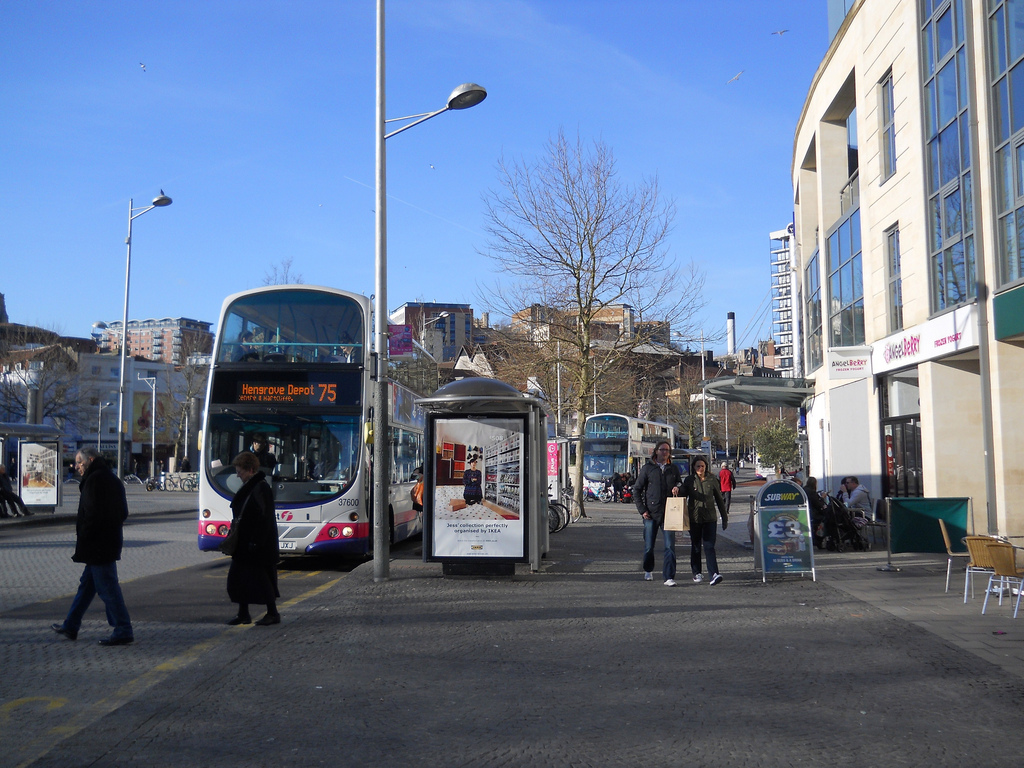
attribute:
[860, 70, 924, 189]
window — blue, black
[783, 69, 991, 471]
building — large, white, huge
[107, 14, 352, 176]
sky — blue, light blue, light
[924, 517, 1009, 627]
chair — yellow, sitting, orange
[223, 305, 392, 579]
bus — moving, white, black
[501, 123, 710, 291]
tree — bare